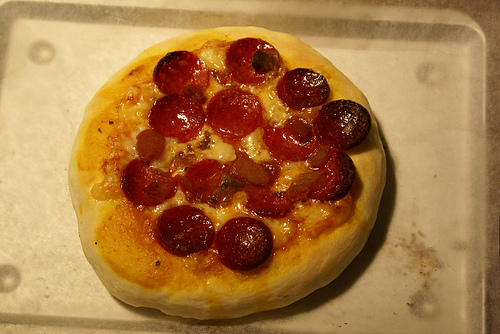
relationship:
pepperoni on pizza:
[164, 91, 328, 165] [36, 51, 394, 248]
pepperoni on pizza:
[273, 64, 332, 109] [70, 27, 389, 319]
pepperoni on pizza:
[214, 217, 274, 272] [62, 70, 373, 290]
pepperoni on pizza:
[120, 158, 179, 207] [70, 27, 389, 319]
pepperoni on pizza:
[154, 205, 214, 257] [70, 27, 389, 319]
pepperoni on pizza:
[214, 217, 274, 272] [70, 27, 389, 319]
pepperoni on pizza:
[182, 156, 230, 202] [70, 27, 389, 319]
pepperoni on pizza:
[244, 185, 294, 217] [70, 27, 389, 319]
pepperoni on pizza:
[322, 105, 374, 147] [70, 27, 389, 319]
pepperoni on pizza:
[206, 88, 264, 139] [70, 27, 389, 319]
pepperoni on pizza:
[202, 90, 283, 144] [155, 71, 403, 268]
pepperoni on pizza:
[214, 217, 274, 272] [58, 14, 399, 331]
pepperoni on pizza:
[311, 99, 372, 150] [82, 22, 404, 309]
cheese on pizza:
[202, 136, 234, 161] [70, 27, 389, 319]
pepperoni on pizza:
[150, 95, 204, 140] [70, 27, 389, 319]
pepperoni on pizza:
[221, 36, 283, 89] [70, 27, 389, 319]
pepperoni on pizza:
[261, 112, 317, 166] [70, 27, 389, 319]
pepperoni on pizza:
[302, 150, 367, 213] [70, 27, 389, 319]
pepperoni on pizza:
[214, 217, 283, 275] [70, 27, 389, 319]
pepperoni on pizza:
[120, 145, 177, 205] [70, 27, 389, 319]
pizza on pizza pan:
[70, 27, 389, 319] [0, 0, 488, 334]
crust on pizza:
[91, 180, 219, 306] [70, 27, 389, 319]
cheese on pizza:
[185, 127, 245, 172] [58, 14, 399, 331]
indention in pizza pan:
[25, 36, 67, 69] [346, 5, 491, 174]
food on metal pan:
[69, 23, 396, 321] [0, 0, 487, 334]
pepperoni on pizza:
[122, 37, 375, 271] [70, 27, 389, 319]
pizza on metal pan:
[70, 27, 389, 319] [0, 0, 487, 334]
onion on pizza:
[125, 122, 170, 160] [70, 27, 389, 319]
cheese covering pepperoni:
[163, 103, 336, 220] [231, 38, 276, 86]